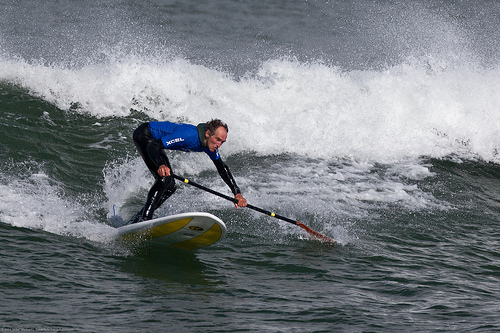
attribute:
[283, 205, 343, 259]
end — red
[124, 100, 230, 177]
man — black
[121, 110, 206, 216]
wetsuit — blue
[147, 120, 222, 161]
shirt — blue, white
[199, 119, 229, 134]
hair — brown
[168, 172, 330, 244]
pole — black, yellow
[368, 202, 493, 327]
water — dark, grey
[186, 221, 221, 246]
stripe — yellow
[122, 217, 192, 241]
stripe — yellow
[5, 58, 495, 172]
wave — white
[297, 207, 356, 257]
paddle — orange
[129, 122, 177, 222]
pants — black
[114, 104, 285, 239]
man — wearing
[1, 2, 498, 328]
water — body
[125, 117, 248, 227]
wetsuit — black, blue